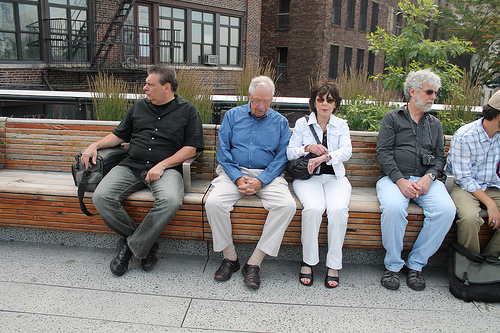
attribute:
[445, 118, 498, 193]
shirt — plaid, blue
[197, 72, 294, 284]
man — looking down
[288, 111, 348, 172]
blouse — white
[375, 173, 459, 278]
jeans — light blue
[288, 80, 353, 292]
woman — wearing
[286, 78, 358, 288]
woman — brown-haired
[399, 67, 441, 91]
hair — grey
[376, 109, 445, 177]
shirt — blue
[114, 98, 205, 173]
shirt — blue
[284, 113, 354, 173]
shirt — blue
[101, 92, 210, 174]
shirt — black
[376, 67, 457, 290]
man — gray-haired, gray haired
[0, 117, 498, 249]
bench — brown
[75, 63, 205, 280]
man — gray-haired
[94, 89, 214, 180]
shirt — black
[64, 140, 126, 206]
suitcase — gray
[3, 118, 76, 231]
bench — brown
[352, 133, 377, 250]
bench — brown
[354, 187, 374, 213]
bench — brown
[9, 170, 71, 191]
bench — brown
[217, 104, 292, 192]
shirt — blue, long  sleeve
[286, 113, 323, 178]
purse — black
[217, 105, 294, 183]
shirt — blue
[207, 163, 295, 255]
pants — khaki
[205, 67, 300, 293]
man — older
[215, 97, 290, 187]
shirt — blue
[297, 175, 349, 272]
pants — white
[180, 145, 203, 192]
arm rest — metal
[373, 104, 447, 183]
shirt — gray